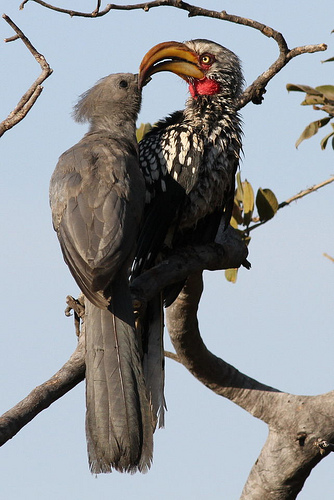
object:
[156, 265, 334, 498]
branch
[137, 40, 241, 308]
bird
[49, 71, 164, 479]
chick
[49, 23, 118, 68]
sky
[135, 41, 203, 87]
beak